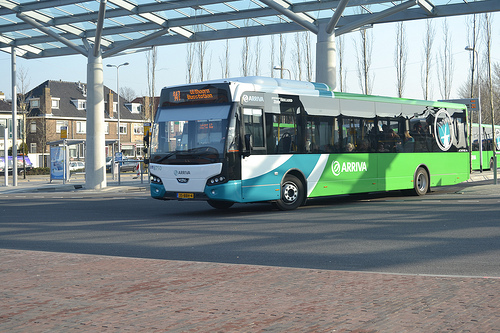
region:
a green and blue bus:
[118, 67, 475, 234]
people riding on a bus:
[363, 122, 417, 147]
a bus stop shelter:
[20, 127, 122, 200]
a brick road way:
[43, 277, 379, 318]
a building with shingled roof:
[18, 77, 138, 134]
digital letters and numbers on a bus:
[151, 72, 231, 119]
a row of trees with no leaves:
[176, 24, 461, 80]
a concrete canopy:
[0, 5, 446, 88]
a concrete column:
[68, 22, 119, 222]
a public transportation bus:
[154, 59, 471, 221]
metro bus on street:
[149, 86, 472, 208]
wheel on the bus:
[270, 176, 307, 217]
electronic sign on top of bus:
[150, 84, 231, 109]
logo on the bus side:
[309, 150, 388, 196]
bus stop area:
[51, 133, 122, 185]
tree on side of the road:
[481, 30, 498, 191]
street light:
[100, 60, 130, 185]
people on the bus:
[299, 127, 414, 157]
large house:
[35, 83, 137, 144]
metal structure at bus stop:
[62, 0, 167, 187]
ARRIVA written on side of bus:
[340, 159, 378, 178]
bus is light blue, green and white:
[271, 152, 375, 194]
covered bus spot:
[46, 130, 123, 184]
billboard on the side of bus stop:
[47, 142, 76, 179]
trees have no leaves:
[336, 28, 453, 97]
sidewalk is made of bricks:
[53, 270, 390, 323]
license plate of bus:
[171, 191, 203, 201]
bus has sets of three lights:
[143, 175, 233, 187]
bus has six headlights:
[150, 176, 247, 187]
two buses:
[440, 119, 498, 174]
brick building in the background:
[1, 74, 157, 174]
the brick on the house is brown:
[13, 75, 155, 170]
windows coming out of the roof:
[71, 98, 85, 110]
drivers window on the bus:
[241, 108, 266, 150]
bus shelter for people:
[50, 140, 120, 186]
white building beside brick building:
[1, 93, 26, 170]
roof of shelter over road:
[1, 4, 489, 56]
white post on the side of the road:
[1, 125, 16, 191]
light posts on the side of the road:
[101, 60, 131, 162]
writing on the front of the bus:
[170, 168, 193, 178]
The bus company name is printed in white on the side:
[336, 156, 379, 173]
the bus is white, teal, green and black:
[145, 77, 475, 209]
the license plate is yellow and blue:
[172, 193, 197, 200]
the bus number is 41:
[167, 86, 182, 103]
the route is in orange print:
[170, 90, 219, 102]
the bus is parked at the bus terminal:
[153, 79, 484, 207]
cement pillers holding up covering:
[17, 13, 137, 194]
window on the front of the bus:
[148, 100, 231, 161]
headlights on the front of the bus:
[148, 173, 163, 185]